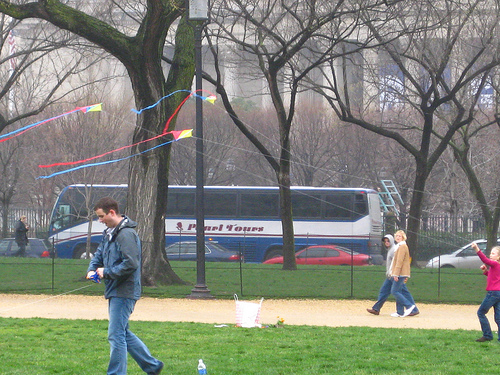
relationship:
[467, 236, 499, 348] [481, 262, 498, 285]
girl wearing a pink shirt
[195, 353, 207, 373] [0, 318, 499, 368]
bottle on a grass field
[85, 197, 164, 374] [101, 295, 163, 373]
man wearing a jean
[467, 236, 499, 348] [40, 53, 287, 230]
girl flying a kite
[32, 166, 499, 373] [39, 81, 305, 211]
people flying kite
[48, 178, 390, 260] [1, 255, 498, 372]
bus outside park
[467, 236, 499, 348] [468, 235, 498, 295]
girl wearing pink shirt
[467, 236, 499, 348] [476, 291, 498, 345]
girl wearing jean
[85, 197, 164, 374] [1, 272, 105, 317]
man holding string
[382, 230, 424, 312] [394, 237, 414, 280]
woman wearing jacket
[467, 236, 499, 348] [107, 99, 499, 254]
girl holding kite string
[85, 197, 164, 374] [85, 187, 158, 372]
man wearing black coat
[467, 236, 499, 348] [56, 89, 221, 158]
girl flying kite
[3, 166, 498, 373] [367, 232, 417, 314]
people walking beside person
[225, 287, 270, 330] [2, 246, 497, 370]
bag on grass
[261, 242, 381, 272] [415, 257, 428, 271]
car on curb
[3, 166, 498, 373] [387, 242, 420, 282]
people in coat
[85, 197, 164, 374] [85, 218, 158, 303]
man wearing black coat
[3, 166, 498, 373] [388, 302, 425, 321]
people wearing shoes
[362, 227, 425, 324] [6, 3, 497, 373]
couple walking in park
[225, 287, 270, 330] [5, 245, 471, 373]
bag on floor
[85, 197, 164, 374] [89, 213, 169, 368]
man in clothes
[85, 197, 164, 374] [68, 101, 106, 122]
man flying kite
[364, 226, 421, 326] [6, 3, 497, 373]
pedestrians walking through park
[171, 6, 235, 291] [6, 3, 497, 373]
lamppost in park